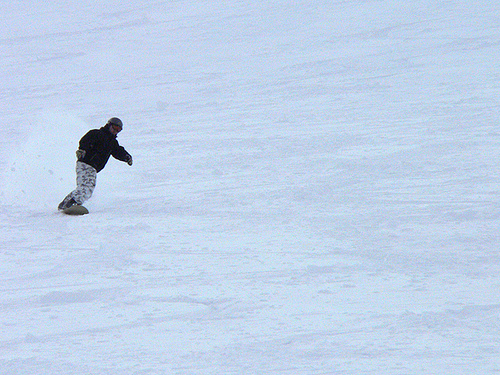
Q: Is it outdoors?
A: Yes, it is outdoors.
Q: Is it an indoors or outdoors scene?
A: It is outdoors.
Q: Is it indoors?
A: No, it is outdoors.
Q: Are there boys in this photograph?
A: No, there are no boys.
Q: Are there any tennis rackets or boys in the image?
A: No, there are no boys or tennis rackets.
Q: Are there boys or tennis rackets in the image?
A: No, there are no boys or tennis rackets.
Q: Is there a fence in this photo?
A: No, there are no fences.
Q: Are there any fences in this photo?
A: No, there are no fences.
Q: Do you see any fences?
A: No, there are no fences.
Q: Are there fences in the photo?
A: No, there are no fences.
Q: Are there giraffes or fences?
A: No, there are no fences or giraffes.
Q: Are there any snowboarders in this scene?
A: Yes, there is a snowboarder.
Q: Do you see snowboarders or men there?
A: Yes, there is a snowboarder.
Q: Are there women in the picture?
A: No, there are no women.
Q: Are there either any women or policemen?
A: No, there are no women or policemen.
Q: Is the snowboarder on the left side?
A: Yes, the snowboarder is on the left of the image.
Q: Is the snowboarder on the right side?
A: No, the snowboarder is on the left of the image.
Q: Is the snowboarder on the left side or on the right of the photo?
A: The snowboarder is on the left of the image.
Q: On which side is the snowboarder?
A: The snowboarder is on the left of the image.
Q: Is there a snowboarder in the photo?
A: Yes, there is a snowboarder.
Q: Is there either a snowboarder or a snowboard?
A: Yes, there is a snowboarder.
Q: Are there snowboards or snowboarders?
A: Yes, there is a snowboarder.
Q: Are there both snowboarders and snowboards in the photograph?
A: Yes, there are both a snowboarder and a snowboard.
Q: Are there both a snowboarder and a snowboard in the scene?
A: Yes, there are both a snowboarder and a snowboard.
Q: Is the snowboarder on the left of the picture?
A: Yes, the snowboarder is on the left of the image.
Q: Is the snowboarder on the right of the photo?
A: No, the snowboarder is on the left of the image.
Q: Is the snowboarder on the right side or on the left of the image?
A: The snowboarder is on the left of the image.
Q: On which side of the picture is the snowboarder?
A: The snowboarder is on the left of the image.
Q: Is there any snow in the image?
A: Yes, there is snow.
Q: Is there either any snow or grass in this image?
A: Yes, there is snow.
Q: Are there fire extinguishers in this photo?
A: No, there are no fire extinguishers.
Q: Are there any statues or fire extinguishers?
A: No, there are no fire extinguishers or statues.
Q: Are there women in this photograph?
A: No, there are no women.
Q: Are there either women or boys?
A: No, there are no women or boys.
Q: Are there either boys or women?
A: No, there are no women or boys.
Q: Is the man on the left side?
A: Yes, the man is on the left of the image.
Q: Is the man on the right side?
A: No, the man is on the left of the image.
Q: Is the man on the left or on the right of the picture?
A: The man is on the left of the image.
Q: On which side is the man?
A: The man is on the left of the image.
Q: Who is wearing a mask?
A: The man is wearing a mask.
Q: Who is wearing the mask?
A: The man is wearing a mask.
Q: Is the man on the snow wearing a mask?
A: Yes, the man is wearing a mask.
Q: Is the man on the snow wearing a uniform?
A: No, the man is wearing a mask.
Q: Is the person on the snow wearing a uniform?
A: No, the man is wearing a mask.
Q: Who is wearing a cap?
A: The man is wearing a cap.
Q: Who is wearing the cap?
A: The man is wearing a cap.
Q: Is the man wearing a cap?
A: Yes, the man is wearing a cap.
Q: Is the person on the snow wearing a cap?
A: Yes, the man is wearing a cap.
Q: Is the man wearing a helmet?
A: No, the man is wearing a cap.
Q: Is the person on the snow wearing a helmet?
A: No, the man is wearing a cap.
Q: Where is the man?
A: The man is on the snow.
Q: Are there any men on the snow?
A: Yes, there is a man on the snow.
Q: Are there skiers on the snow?
A: No, there is a man on the snow.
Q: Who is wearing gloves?
A: The man is wearing gloves.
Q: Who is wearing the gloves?
A: The man is wearing gloves.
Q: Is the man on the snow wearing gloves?
A: Yes, the man is wearing gloves.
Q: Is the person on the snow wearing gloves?
A: Yes, the man is wearing gloves.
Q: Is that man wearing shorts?
A: No, the man is wearing gloves.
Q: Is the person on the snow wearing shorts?
A: No, the man is wearing gloves.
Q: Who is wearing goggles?
A: The man is wearing goggles.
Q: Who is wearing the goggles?
A: The man is wearing goggles.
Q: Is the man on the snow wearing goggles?
A: Yes, the man is wearing goggles.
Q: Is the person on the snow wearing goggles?
A: Yes, the man is wearing goggles.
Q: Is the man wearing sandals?
A: No, the man is wearing goggles.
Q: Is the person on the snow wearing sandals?
A: No, the man is wearing goggles.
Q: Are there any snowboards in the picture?
A: Yes, there is a snowboard.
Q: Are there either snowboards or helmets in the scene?
A: Yes, there is a snowboard.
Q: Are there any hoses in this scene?
A: No, there are no hoses.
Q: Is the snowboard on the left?
A: Yes, the snowboard is on the left of the image.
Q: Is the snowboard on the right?
A: No, the snowboard is on the left of the image.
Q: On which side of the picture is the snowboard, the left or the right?
A: The snowboard is on the left of the image.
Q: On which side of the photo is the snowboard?
A: The snowboard is on the left of the image.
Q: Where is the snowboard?
A: The snowboard is in the snow.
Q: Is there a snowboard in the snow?
A: Yes, there is a snowboard in the snow.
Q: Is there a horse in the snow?
A: No, there is a snowboard in the snow.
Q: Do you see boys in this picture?
A: No, there are no boys.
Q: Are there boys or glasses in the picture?
A: No, there are no boys or glasses.